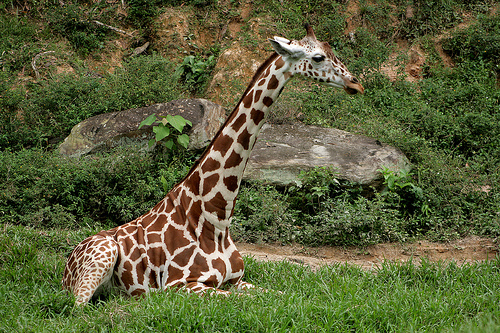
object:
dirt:
[261, 231, 481, 268]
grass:
[2, 224, 496, 331]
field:
[1, 217, 498, 331]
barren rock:
[246, 120, 420, 192]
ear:
[264, 33, 304, 61]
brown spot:
[203, 197, 229, 217]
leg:
[63, 237, 119, 316]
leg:
[172, 282, 255, 304]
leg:
[239, 271, 284, 296]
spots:
[118, 255, 148, 290]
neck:
[157, 53, 289, 219]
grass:
[3, 34, 497, 240]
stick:
[93, 20, 142, 47]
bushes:
[1, 56, 179, 147]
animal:
[64, 23, 364, 310]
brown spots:
[308, 54, 349, 85]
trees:
[0, 52, 193, 144]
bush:
[362, 51, 484, 196]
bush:
[16, 147, 141, 217]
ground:
[2, 0, 496, 327]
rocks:
[53, 97, 228, 163]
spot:
[196, 154, 220, 185]